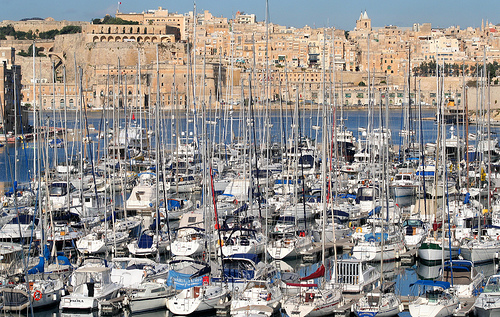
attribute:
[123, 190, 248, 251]
ships — still, white, curved, larg, moored, distant, cruiser, huge, docked, large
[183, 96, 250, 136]
poles — above, thin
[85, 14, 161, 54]
building — here, tan, across, wide, background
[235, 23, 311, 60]
wall — brown, here, concrete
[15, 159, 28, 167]
water — blue, body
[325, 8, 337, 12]
sky — here, blue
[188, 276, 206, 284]
masts — burgundy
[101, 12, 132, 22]
trees — here, green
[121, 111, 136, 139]
buoy — orange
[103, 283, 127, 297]
tender — inflatable